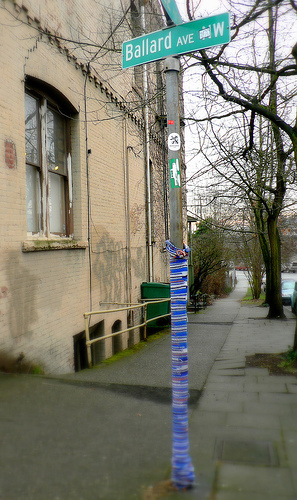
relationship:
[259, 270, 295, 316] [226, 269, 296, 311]
cars parked on road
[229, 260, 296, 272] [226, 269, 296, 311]
cars parked on road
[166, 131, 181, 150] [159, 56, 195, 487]
sticker on pole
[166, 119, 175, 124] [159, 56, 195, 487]
sticker on pole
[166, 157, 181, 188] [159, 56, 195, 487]
sticker on pole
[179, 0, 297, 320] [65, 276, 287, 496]
tree on sidewalk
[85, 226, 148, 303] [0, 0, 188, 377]
graffiti on building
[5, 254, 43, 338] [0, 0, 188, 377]
graffiti on building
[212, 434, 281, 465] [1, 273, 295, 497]
plate on sidewalk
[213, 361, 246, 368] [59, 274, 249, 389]
raised block on sidewalk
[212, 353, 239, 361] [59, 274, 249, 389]
raised block on sidewalk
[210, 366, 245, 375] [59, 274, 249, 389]
raised block on sidewalk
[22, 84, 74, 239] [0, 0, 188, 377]
window in side of building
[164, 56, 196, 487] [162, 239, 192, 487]
pole on pole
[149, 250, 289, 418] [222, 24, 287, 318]
sidewalk lined in tree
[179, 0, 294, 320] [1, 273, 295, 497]
tree planted on sidewalk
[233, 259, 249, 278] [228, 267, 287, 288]
cars road parked in distance at end of road